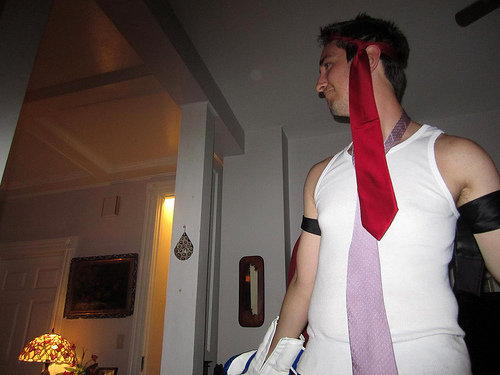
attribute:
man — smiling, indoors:
[258, 14, 498, 375]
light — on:
[160, 196, 176, 224]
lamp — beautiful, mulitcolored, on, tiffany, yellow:
[17, 328, 78, 375]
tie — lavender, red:
[329, 32, 400, 243]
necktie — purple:
[345, 108, 413, 375]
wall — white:
[0, 179, 150, 373]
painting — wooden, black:
[63, 251, 141, 321]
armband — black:
[298, 214, 322, 238]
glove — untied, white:
[220, 313, 307, 374]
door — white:
[0, 245, 71, 374]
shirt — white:
[295, 122, 473, 374]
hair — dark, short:
[317, 11, 411, 107]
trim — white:
[24, 62, 167, 118]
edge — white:
[124, 178, 166, 372]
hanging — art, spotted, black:
[174, 224, 195, 262]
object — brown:
[238, 257, 266, 328]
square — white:
[101, 194, 120, 217]